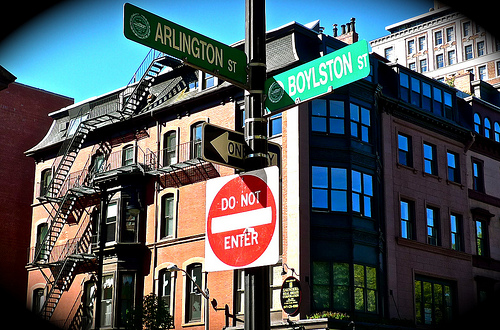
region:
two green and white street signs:
[115, 13, 395, 123]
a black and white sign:
[191, 120, 303, 177]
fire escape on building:
[28, 86, 150, 323]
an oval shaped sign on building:
[277, 267, 311, 328]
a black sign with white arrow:
[203, 127, 293, 178]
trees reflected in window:
[313, 259, 383, 316]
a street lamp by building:
[147, 252, 231, 329]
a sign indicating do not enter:
[197, 168, 284, 286]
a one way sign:
[182, 120, 294, 167]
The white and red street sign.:
[202, 180, 283, 272]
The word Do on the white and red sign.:
[220, 193, 236, 212]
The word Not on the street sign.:
[241, 190, 258, 205]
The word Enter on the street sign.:
[224, 235, 258, 248]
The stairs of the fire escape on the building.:
[26, 50, 181, 328]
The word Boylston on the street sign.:
[290, 54, 355, 101]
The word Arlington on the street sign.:
[153, 18, 230, 73]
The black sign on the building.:
[281, 273, 299, 319]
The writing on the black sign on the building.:
[282, 276, 298, 312]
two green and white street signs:
[121, 2, 380, 121]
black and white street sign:
[200, 123, 285, 170]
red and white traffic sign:
[204, 158, 288, 267]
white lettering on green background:
[151, 18, 221, 69]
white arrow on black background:
[208, 132, 279, 168]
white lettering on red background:
[219, 186, 261, 252]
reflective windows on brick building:
[303, 47, 488, 316]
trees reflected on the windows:
[315, 261, 461, 313]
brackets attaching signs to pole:
[239, 61, 265, 165]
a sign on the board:
[197, 179, 280, 294]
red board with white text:
[204, 185, 293, 292]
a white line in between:
[208, 213, 279, 238]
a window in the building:
[147, 188, 194, 244]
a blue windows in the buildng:
[317, 160, 387, 218]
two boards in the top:
[113, 15, 360, 100]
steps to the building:
[27, 173, 110, 329]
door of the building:
[160, 253, 205, 324]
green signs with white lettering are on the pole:
[117, 1, 372, 120]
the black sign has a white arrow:
[196, 122, 286, 182]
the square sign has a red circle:
[200, 165, 285, 277]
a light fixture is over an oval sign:
[276, 260, 304, 317]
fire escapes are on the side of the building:
[26, 46, 189, 328]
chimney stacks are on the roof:
[331, 18, 359, 45]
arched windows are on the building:
[36, 118, 243, 328]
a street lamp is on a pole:
[157, 258, 212, 328]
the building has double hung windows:
[307, 45, 474, 324]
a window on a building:
[308, 92, 326, 134]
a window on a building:
[423, 143, 435, 171]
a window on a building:
[325, 95, 340, 132]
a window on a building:
[346, 98, 356, 139]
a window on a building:
[310, 166, 328, 211]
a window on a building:
[326, 167, 342, 212]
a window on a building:
[347, 165, 363, 215]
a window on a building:
[361, 172, 367, 215]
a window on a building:
[396, 198, 408, 242]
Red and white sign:
[193, 168, 283, 278]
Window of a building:
[396, 195, 418, 242]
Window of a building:
[420, 200, 442, 245]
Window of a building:
[448, 208, 470, 255]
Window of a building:
[421, 138, 438, 177]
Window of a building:
[443, 148, 459, 183]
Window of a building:
[471, 159, 487, 193]